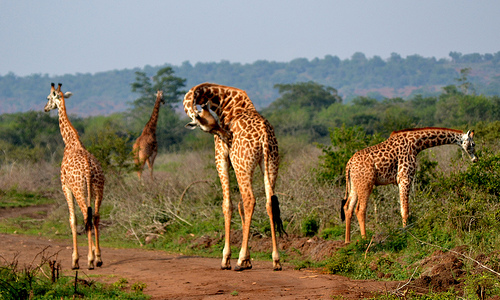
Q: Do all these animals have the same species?
A: Yes, all the animals are giraffes.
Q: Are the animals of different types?
A: No, all the animals are giraffes.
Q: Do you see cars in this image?
A: No, there are no cars.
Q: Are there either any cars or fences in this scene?
A: No, there are no cars or fences.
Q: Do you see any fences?
A: No, there are no fences.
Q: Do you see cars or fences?
A: No, there are no fences or cars.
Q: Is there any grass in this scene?
A: Yes, there is grass.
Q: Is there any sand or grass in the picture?
A: Yes, there is grass.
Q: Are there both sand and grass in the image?
A: No, there is grass but no sand.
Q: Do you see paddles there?
A: No, there are no paddles.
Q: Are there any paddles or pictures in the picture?
A: No, there are no paddles or pictures.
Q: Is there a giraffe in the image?
A: Yes, there is a giraffe.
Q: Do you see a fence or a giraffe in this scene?
A: Yes, there is a giraffe.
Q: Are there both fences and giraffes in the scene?
A: No, there is a giraffe but no fences.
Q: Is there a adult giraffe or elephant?
A: Yes, there is an adult giraffe.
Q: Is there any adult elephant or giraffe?
A: Yes, there is an adult giraffe.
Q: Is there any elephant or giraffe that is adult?
A: Yes, the giraffe is adult.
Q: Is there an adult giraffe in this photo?
A: Yes, there is an adult giraffe.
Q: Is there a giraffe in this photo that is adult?
A: Yes, there is a giraffe that is adult.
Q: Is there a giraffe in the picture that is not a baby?
A: Yes, there is a adult giraffe.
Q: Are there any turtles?
A: No, there are no turtles.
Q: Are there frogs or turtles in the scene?
A: No, there are no turtles or frogs.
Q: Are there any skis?
A: No, there are no skis.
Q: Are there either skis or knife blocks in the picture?
A: No, there are no skis or knife blocks.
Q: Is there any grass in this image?
A: Yes, there is grass.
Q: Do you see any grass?
A: Yes, there is grass.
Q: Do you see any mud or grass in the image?
A: Yes, there is grass.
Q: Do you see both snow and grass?
A: No, there is grass but no snow.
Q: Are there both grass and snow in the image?
A: No, there is grass but no snow.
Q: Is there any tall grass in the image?
A: Yes, there is tall grass.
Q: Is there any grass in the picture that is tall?
A: Yes, there is tall grass.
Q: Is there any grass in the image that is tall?
A: Yes, there is grass that is tall.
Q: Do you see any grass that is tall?
A: Yes, there is grass that is tall.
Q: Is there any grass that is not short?
A: Yes, there is tall grass.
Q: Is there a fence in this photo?
A: No, there are no fences.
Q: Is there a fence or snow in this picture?
A: No, there are no fences or snow.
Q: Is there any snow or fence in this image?
A: No, there are no fences or snow.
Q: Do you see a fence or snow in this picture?
A: No, there are no fences or snow.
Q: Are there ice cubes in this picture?
A: No, there are no ice cubes.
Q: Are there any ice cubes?
A: No, there are no ice cubes.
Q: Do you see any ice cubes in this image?
A: No, there are no ice cubes.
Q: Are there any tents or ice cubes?
A: No, there are no ice cubes or tents.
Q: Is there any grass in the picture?
A: Yes, there is grass.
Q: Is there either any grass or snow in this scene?
A: Yes, there is grass.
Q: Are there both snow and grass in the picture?
A: No, there is grass but no snow.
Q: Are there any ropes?
A: No, there are no ropes.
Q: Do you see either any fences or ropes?
A: No, there are no ropes or fences.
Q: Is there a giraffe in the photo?
A: Yes, there is a giraffe.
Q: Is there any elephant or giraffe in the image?
A: Yes, there is a giraffe.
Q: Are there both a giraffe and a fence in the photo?
A: No, there is a giraffe but no fences.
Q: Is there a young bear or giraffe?
A: Yes, there is a young giraffe.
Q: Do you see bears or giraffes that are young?
A: Yes, the giraffe is young.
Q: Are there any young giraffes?
A: Yes, there is a young giraffe.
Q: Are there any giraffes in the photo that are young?
A: Yes, there is a giraffe that is young.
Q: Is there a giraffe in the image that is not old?
A: Yes, there is an young giraffe.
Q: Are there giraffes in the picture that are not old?
A: Yes, there is an young giraffe.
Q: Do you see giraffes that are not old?
A: Yes, there is an young giraffe.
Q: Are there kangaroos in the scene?
A: No, there are no kangaroos.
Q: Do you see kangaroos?
A: No, there are no kangaroos.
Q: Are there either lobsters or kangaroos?
A: No, there are no kangaroos or lobsters.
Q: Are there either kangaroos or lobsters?
A: No, there are no kangaroos or lobsters.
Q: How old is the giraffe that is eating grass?
A: The giraffe is young.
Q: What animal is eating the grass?
A: The giraffe is eating the grass.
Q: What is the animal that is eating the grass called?
A: The animal is a giraffe.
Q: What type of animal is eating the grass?
A: The animal is a giraffe.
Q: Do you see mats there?
A: No, there are no mats.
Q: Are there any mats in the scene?
A: No, there are no mats.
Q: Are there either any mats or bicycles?
A: No, there are no mats or bicycles.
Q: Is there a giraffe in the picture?
A: Yes, there is a giraffe.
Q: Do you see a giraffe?
A: Yes, there is a giraffe.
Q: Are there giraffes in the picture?
A: Yes, there is a giraffe.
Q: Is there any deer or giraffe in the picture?
A: Yes, there is a giraffe.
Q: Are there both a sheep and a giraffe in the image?
A: No, there is a giraffe but no sheep.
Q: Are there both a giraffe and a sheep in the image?
A: No, there is a giraffe but no sheep.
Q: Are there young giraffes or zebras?
A: Yes, there is a young giraffe.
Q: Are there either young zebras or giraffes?
A: Yes, there is a young giraffe.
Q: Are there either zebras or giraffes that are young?
A: Yes, the giraffe is young.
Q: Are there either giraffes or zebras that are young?
A: Yes, the giraffe is young.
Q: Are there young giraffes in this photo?
A: Yes, there is a young giraffe.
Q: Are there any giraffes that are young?
A: Yes, there is a giraffe that is young.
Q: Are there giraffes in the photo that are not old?
A: Yes, there is an young giraffe.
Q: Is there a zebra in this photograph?
A: No, there are no zebras.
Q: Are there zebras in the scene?
A: No, there are no zebras.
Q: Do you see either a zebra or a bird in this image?
A: No, there are no zebras or birds.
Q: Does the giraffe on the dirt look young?
A: Yes, the giraffe is young.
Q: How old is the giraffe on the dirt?
A: The giraffe is young.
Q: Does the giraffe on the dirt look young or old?
A: The giraffe is young.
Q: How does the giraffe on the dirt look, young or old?
A: The giraffe is young.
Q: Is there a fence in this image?
A: No, there are no fences.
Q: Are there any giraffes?
A: Yes, there is a giraffe.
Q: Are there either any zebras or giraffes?
A: Yes, there is a giraffe.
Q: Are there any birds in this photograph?
A: No, there are no birds.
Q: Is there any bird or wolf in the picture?
A: No, there are no birds or wolves.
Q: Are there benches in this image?
A: No, there are no benches.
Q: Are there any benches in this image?
A: No, there are no benches.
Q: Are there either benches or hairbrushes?
A: No, there are no benches or hairbrushes.